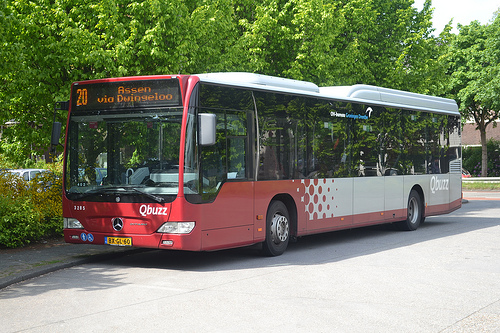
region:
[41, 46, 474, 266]
the bus is red and white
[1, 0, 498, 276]
big green trees behind the bus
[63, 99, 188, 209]
the bus has a big window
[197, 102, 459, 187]
the bus has big windows on the side of it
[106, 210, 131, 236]
a mercedes symbol on the front of the bus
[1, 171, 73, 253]
bushes beside the bus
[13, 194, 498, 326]
the road is gray and dry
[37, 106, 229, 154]
the bus has two big side mirrors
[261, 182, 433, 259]
the tires are black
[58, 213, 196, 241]
the bus has head lights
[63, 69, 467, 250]
the bus on the road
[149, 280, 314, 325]
the road is paved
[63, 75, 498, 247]
the bus is number 20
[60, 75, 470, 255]
the bus is red and gray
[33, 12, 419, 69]
the trees with green the leaves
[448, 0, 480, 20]
the clear blue sky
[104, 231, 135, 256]
the license plate on the bus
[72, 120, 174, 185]
the windshield of the bus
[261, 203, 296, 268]
the front tire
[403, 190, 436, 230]
the rear tire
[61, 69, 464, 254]
a red and white bus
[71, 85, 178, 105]
electronic bus destination sign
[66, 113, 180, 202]
a bus' front windshield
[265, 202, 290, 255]
a bus' front tire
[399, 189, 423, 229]
a bus' rear tire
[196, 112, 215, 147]
a bus' rear view mirror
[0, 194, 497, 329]
a paved city street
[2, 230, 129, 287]
a paved city sidewalk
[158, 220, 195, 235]
a bus' front headlight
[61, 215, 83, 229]
a bus' front headlight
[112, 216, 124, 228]
Mercedes-Benz logo on the front of the bus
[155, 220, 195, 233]
Headlight of a passenger bus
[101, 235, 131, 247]
License plate on a passenger bus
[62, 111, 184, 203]
Windshield on a passenger bus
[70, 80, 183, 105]
Electronic sign on a passenger bus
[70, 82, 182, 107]
Sign displaying a route on a passenger bus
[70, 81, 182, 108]
Bus number and route on a passenger bus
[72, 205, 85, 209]
ID number on a passenger bus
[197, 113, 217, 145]
Rearview mirror on a passenger bus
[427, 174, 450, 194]
Company name on a passenger bus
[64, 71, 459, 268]
Dark red bus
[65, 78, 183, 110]
Digital reader describing the location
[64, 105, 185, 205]
Front window of the bus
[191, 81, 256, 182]
Left side window of the bus driver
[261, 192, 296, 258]
Left front wheel of the bus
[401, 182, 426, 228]
Back left wheel of the bus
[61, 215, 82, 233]
Right front light of the bus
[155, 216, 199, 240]
Left front light of the bus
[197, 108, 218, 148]
Left mirror of the bus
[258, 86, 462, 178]
Left panel of windows for the passengers